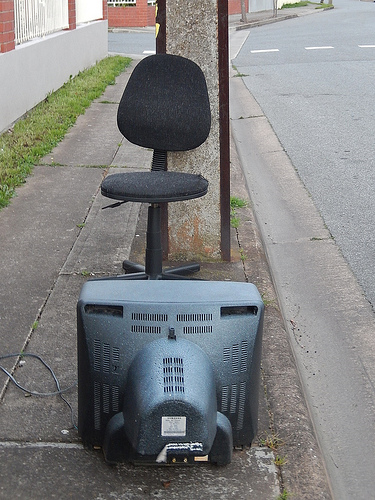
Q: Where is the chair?
A: On the sidewalk.